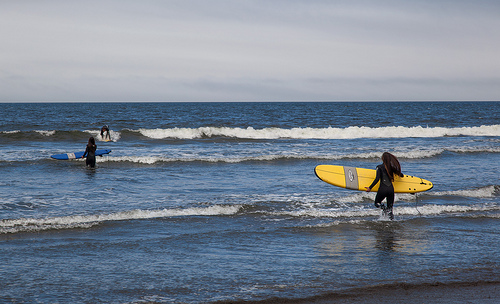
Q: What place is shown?
A: It is an ocean.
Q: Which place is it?
A: It is an ocean.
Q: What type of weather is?
A: It is cloudy.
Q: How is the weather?
A: It is cloudy.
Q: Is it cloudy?
A: Yes, it is cloudy.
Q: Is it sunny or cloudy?
A: It is cloudy.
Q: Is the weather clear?
A: No, it is cloudy.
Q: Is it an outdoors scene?
A: Yes, it is outdoors.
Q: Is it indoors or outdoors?
A: It is outdoors.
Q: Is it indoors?
A: No, it is outdoors.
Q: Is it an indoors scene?
A: No, it is outdoors.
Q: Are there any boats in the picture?
A: No, there are no boats.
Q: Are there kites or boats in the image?
A: No, there are no boats or kites.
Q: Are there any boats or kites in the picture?
A: No, there are no boats or kites.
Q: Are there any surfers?
A: Yes, there is a surfer.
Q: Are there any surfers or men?
A: Yes, there is a surfer.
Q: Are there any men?
A: No, there are no men.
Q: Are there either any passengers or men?
A: No, there are no men or passengers.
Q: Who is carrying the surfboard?
A: The surfer is carrying the surfboard.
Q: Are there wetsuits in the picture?
A: Yes, there is a wetsuit.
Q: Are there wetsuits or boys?
A: Yes, there is a wetsuit.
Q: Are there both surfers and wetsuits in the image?
A: Yes, there are both a wetsuit and a surfer.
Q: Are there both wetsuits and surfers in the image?
A: Yes, there are both a wetsuit and a surfer.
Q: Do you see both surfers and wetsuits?
A: Yes, there are both a wetsuit and a surfer.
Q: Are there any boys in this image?
A: No, there are no boys.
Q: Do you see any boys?
A: No, there are no boys.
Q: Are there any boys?
A: No, there are no boys.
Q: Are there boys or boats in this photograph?
A: No, there are no boys or boats.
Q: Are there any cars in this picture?
A: No, there are no cars.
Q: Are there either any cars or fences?
A: No, there are no cars or fences.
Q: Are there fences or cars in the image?
A: No, there are no cars or fences.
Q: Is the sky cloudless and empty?
A: No, the sky is empty but cloudy.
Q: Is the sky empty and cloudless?
A: No, the sky is empty but cloudy.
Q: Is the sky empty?
A: Yes, the sky is empty.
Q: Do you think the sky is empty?
A: Yes, the sky is empty.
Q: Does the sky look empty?
A: Yes, the sky is empty.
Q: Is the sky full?
A: No, the sky is empty.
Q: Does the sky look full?
A: No, the sky is empty.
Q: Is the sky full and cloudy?
A: No, the sky is cloudy but empty.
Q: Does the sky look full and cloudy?
A: No, the sky is cloudy but empty.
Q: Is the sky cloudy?
A: Yes, the sky is cloudy.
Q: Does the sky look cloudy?
A: Yes, the sky is cloudy.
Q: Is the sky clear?
A: No, the sky is cloudy.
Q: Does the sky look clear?
A: No, the sky is cloudy.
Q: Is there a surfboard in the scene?
A: Yes, there is a surfboard.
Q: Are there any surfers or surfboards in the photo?
A: Yes, there is a surfboard.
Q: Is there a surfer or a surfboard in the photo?
A: Yes, there is a surfboard.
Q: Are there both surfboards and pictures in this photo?
A: No, there is a surfboard but no pictures.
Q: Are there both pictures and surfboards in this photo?
A: No, there is a surfboard but no pictures.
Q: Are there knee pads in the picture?
A: No, there are no knee pads.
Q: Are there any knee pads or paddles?
A: No, there are no knee pads or paddles.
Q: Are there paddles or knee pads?
A: No, there are no knee pads or paddles.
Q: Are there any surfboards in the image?
A: Yes, there is a surfboard.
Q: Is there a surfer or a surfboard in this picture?
A: Yes, there is a surfboard.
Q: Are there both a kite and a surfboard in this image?
A: No, there is a surfboard but no kites.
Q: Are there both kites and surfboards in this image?
A: No, there is a surfboard but no kites.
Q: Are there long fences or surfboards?
A: Yes, there is a long surfboard.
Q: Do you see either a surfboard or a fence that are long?
A: Yes, the surfboard is long.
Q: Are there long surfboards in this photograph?
A: Yes, there is a long surfboard.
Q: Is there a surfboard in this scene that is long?
A: Yes, there is a surfboard that is long.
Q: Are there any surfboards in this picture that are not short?
A: Yes, there is a long surfboard.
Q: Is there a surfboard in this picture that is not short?
A: Yes, there is a long surfboard.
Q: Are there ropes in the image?
A: No, there are no ropes.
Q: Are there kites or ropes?
A: No, there are no ropes or kites.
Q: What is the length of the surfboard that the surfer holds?
A: The surfboard is long.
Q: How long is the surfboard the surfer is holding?
A: The surfboard is long.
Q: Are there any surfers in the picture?
A: Yes, there is a surfer.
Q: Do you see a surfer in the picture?
A: Yes, there is a surfer.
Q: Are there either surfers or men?
A: Yes, there is a surfer.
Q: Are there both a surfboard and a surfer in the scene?
A: Yes, there are both a surfer and a surfboard.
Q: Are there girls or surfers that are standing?
A: Yes, the surfer is standing.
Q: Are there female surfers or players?
A: Yes, there is a female surfer.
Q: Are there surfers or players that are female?
A: Yes, the surfer is female.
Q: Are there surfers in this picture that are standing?
A: Yes, there is a surfer that is standing.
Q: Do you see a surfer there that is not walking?
A: Yes, there is a surfer that is standing .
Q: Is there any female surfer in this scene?
A: Yes, there is a female surfer.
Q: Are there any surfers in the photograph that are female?
A: Yes, there is a surfer that is female.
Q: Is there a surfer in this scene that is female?
A: Yes, there is a surfer that is female.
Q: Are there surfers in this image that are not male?
A: Yes, there is a female surfer.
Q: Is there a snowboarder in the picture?
A: No, there are no snowboarders.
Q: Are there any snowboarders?
A: No, there are no snowboarders.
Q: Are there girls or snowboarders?
A: No, there are no snowboarders or girls.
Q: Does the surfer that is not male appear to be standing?
A: Yes, the surfer is standing.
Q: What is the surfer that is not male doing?
A: The surfer is standing.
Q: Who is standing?
A: The surfer is standing.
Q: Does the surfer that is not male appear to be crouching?
A: No, the surfer is standing.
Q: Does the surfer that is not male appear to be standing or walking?
A: The surfer is standing.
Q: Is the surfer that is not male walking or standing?
A: The surfer is standing.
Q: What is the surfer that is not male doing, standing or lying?
A: The surfer is standing.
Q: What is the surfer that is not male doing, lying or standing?
A: The surfer is standing.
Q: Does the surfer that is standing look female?
A: Yes, the surfer is female.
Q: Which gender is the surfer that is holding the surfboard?
A: The surfer is female.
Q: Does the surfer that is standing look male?
A: No, the surfer is female.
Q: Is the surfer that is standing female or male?
A: The surfer is female.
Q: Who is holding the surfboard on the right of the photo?
A: The surfer is holding the surfboard.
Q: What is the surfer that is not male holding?
A: The surfer is holding the surfboard.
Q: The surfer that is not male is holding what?
A: The surfer is holding the surfboard.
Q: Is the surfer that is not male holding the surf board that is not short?
A: Yes, the surfer is holding the surfboard.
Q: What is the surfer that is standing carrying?
A: The surfer is carrying a surfboard.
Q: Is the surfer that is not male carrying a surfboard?
A: Yes, the surfer is carrying a surfboard.